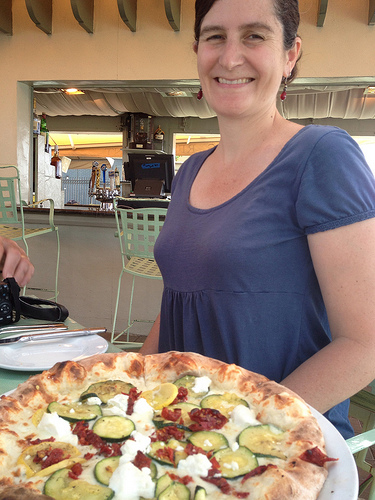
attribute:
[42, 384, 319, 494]
tomato — sun dried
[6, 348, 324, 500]
crust — golden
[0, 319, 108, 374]
plate — white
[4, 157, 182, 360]
stools — pale blue, tall, white, green, blue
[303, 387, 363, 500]
platter — white, large, round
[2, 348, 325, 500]
pizza — here, delicious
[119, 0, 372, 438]
lady — smiling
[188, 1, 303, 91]
hair — brown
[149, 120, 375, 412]
shirt — blue, purple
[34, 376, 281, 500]
zucchini — cooked, sliced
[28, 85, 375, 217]
kitchen — in restaurant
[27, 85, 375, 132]
awning — white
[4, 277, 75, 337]
strap — black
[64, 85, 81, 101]
light — small, recessed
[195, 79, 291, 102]
earrings — red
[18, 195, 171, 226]
bar — here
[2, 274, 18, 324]
camera — black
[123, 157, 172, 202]
cash register — black